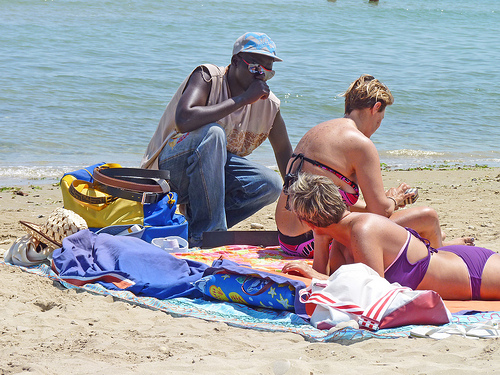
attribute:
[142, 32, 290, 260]
man — kneeling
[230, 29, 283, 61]
cap — blue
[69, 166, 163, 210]
belts — brown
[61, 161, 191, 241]
bag — yellow, blue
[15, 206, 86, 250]
hat — straw, cream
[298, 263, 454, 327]
bag — white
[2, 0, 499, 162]
water — calm, ocean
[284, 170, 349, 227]
hair — frosted, short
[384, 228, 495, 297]
bikini — purple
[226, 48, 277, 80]
sunglasses — red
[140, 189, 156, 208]
buckle — silver